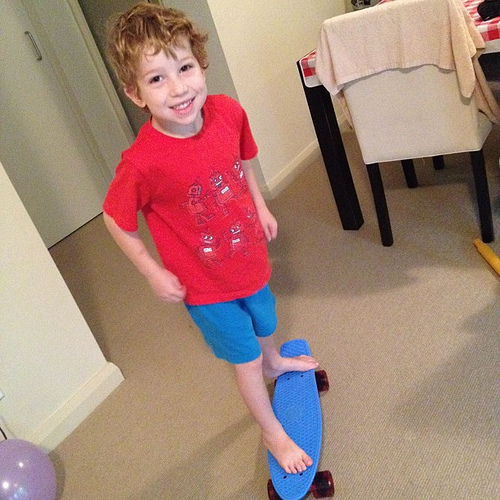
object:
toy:
[471, 234, 500, 277]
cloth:
[308, 2, 480, 84]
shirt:
[111, 128, 267, 297]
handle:
[23, 27, 49, 64]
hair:
[105, 0, 211, 81]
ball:
[0, 436, 62, 500]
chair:
[326, 6, 500, 240]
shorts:
[187, 284, 276, 357]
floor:
[331, 243, 500, 498]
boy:
[97, 8, 311, 473]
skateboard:
[268, 340, 320, 499]